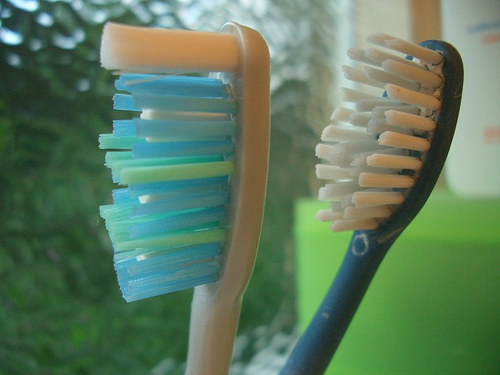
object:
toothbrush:
[94, 20, 270, 375]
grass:
[0, 301, 96, 375]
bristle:
[310, 32, 443, 234]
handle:
[276, 240, 377, 375]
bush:
[15, 83, 98, 186]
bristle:
[96, 21, 238, 303]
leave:
[46, 21, 105, 66]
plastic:
[287, 191, 499, 375]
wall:
[339, 0, 499, 199]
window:
[290, 0, 353, 83]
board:
[332, 0, 465, 193]